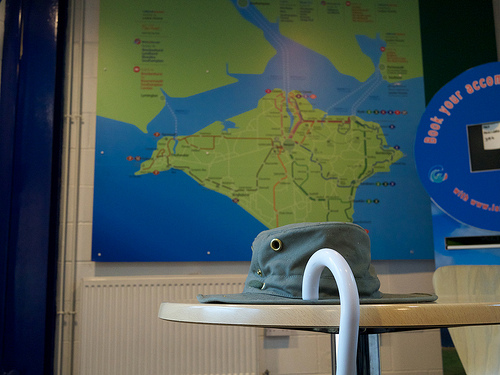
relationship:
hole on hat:
[265, 230, 282, 254] [196, 220, 440, 305]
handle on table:
[268, 218, 401, 363] [166, 256, 478, 338]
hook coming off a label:
[300, 245, 364, 373] [291, 245, 363, 368]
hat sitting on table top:
[190, 197, 450, 317] [154, 294, 484, 336]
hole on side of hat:
[269, 238, 283, 252] [196, 220, 440, 305]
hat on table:
[195, 220, 438, 307] [146, 290, 498, 335]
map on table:
[92, 1, 438, 273] [150, 291, 499, 369]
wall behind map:
[63, 2, 443, 374] [92, 1, 438, 273]